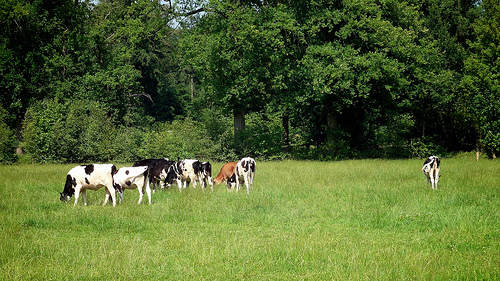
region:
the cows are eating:
[32, 138, 294, 232]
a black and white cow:
[411, 144, 450, 202]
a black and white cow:
[405, 133, 467, 207]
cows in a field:
[62, 78, 449, 278]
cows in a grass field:
[29, 98, 450, 276]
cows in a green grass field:
[74, 101, 488, 241]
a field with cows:
[75, 138, 460, 276]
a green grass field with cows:
[61, 133, 358, 279]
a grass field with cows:
[42, 141, 376, 276]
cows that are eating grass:
[40, 111, 314, 248]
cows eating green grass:
[24, 118, 321, 280]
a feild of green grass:
[62, 133, 421, 277]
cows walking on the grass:
[19, 76, 496, 248]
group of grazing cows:
[51, 156, 263, 210]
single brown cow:
[207, 155, 237, 190]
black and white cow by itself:
[417, 148, 440, 193]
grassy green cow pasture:
[5, 142, 497, 279]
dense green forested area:
[0, 0, 497, 168]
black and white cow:
[43, 163, 122, 210]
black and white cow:
[100, 165, 154, 202]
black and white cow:
[231, 146, 258, 190]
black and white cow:
[157, 156, 204, 193]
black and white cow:
[129, 153, 166, 189]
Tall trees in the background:
[0, 0, 499, 157]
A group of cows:
[44, 135, 261, 218]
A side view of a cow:
[49, 155, 121, 217]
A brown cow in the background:
[207, 154, 241, 194]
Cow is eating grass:
[49, 154, 121, 207]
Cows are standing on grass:
[3, 158, 295, 279]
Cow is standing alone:
[406, 141, 453, 201]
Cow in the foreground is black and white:
[52, 155, 126, 212]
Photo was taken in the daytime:
[1, 1, 496, 276]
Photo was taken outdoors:
[0, 5, 495, 271]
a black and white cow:
[60, 161, 119, 208]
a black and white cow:
[422, 154, 442, 189]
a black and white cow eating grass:
[228, 157, 255, 191]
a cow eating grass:
[164, 157, 211, 191]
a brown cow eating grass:
[212, 158, 234, 187]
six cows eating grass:
[58, 155, 255, 205]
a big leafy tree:
[179, 0, 305, 155]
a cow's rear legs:
[102, 180, 119, 207]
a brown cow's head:
[210, 173, 223, 186]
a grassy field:
[0, 158, 499, 280]